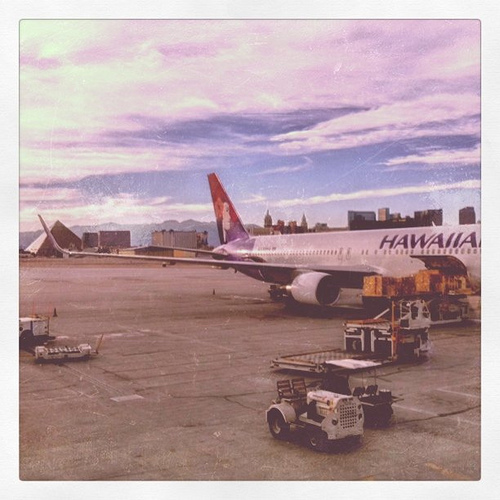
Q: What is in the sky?
A: Clouds.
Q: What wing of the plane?
A: Right.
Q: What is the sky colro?
A: Pink.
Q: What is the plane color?
A: White.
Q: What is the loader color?
A: White.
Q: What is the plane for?
A: Hawaii.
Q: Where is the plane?
A: Airport.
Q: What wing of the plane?
A: Left.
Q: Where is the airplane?
A: Parked at an airport.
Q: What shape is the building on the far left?
A: Pyramid.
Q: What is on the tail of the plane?
A: A woman's face.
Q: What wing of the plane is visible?
A: The right wing.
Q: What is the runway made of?
A: Concrete.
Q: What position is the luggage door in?
A: Open.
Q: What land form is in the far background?
A: Mountains.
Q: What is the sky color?
A: Purple.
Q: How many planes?
A: 1.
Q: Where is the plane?
A: On the strip.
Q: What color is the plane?
A: White.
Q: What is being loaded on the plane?
A: Containers.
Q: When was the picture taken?
A: Daytime.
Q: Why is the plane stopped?
A: Being loaded.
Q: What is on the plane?
A: Hawaiian.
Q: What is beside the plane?
A: A truck.